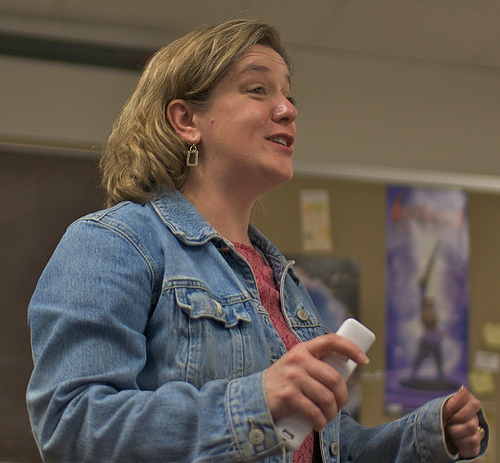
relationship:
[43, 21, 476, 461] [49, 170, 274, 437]
woman wearing jacket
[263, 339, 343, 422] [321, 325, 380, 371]
hand holding remote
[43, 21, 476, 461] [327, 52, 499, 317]
woman in room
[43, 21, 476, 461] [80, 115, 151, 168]
woman has hair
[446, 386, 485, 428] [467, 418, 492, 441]
finger has ring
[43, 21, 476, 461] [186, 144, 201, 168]
woman wearing earring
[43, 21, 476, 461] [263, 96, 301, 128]
woman has nose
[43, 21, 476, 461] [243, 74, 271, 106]
woman has eye